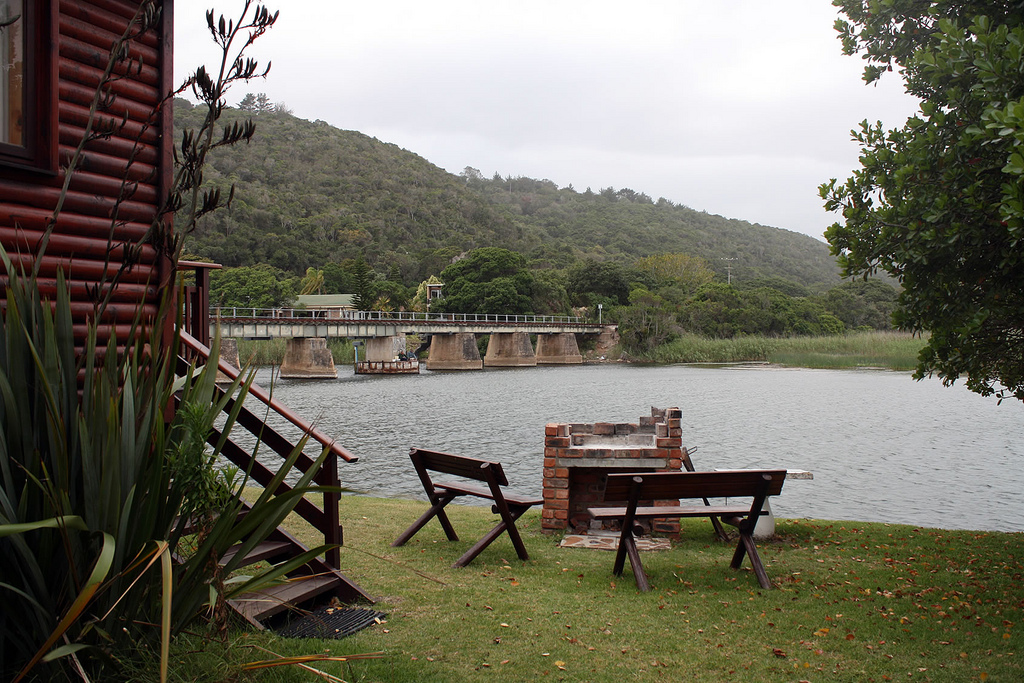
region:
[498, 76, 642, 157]
a view of sky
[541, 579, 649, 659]
a view of grass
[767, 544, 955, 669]
a view of stones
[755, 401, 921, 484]
a view of water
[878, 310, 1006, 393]
a view of plant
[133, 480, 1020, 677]
the grass is cut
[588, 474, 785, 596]
the benches are made of wood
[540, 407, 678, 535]
the fireplace has brick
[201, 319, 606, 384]
the bridge is beige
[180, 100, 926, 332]
the mountains have trees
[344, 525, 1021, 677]
the leaves are on the ground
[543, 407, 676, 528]
the bricks are brown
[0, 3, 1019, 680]
the scene takes place outdoors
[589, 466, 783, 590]
the bench is brown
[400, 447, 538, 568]
bench made of wood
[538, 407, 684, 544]
chimney made of bricks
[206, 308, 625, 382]
bridge over the water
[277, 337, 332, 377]
the support is brown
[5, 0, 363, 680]
plants near the building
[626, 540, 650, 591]
leg of the bench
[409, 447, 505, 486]
back of the bench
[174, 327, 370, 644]
stairs by the building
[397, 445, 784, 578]
simple wooden benches by lake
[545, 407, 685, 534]
half built fire pit by lake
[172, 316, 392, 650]
slanted stairs leading to back of house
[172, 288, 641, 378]
a concrete bridge crossing a lake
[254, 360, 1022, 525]
a large lake near a bridge and house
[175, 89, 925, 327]
a large tree filled hill near lake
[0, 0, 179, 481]
cabin style house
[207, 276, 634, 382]
a bridge in the distance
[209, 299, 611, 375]
the side of the bridge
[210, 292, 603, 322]
the bridge railing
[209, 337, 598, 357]
the lower part of the bridge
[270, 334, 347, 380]
one of the bridges supports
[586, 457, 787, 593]
a bench on the ground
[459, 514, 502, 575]
one of the benches legs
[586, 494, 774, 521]
the seat of the bench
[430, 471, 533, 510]
the seat of the bench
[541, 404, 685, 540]
Broken outdoor brick fireplace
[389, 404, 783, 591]
Brick fireplace and benches beside lake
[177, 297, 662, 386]
Bridge across a small lake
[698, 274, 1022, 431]
Trees and field along a small lake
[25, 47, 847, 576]
House beside lake with benches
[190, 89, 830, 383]
Lush green hillside behind small lake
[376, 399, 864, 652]
Small sitting area beside a lake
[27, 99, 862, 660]
House with a view of a bridge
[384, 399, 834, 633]
Wooden benches and fireplace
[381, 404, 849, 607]
Small brick oven in yard beside lake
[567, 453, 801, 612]
bench on right by bricks